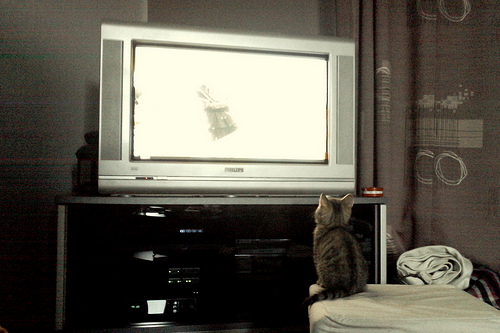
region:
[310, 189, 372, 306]
small grey and black kitten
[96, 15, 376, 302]
kitten watching television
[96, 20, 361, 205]
silver flat screen tv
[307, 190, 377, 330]
cat sitting on a chair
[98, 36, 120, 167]
speaker on side of tv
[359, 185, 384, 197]
red container on table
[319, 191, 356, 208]
ears of grey kitten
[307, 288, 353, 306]
grey and black striped tail on kitten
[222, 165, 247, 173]
logo on front of tv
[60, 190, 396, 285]
table tv is sitting on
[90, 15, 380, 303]
kitten watching TV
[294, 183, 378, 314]
a kitten is color brown and black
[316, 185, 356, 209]
ears of cat are brown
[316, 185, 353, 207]
ears of cat are pointy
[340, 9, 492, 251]
a curtain color brown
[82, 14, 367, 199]
TV is turn on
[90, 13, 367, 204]
TV is color silver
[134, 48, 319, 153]
a cartoon program on TV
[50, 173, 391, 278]
TV is on a metal table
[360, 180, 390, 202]
a red bottle on side of TV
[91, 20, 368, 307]
a cute kitten is watching tv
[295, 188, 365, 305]
the kitten is sitting on an ottoman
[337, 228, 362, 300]
the kitten has a black stripe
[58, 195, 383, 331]
electronic components are under the tv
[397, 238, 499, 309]
blankets are in the corner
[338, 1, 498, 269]
curtains are on the wall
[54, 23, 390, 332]
the tv is on a cabinet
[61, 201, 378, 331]
the cabinet has dark glass doors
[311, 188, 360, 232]
the kitten's head is facing upwards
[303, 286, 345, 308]
the kitty's tail is black and gray stripes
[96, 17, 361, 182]
tv on a stand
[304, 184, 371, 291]
kitten sitting on bed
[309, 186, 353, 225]
head of small cat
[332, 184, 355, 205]
ear of the kitten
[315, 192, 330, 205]
ear of the kitten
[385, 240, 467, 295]
laundry rolled up in bundle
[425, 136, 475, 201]
pattern on a curtain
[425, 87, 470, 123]
pattern on a curtain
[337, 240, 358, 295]
back of small kitten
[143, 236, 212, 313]
stereo under the tv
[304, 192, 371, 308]
a small multicolored kitten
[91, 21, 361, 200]
a phillips monitor gray in color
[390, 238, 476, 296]
a rolled up cloth item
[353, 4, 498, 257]
a brown curtain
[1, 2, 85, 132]
a gray painted wall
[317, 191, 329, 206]
the ear of a small kitten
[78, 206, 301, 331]
different electronic equipment in a stand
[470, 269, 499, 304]
a multicolored blanket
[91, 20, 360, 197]
a monitor with something on it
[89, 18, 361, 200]
a tv screen with no show on